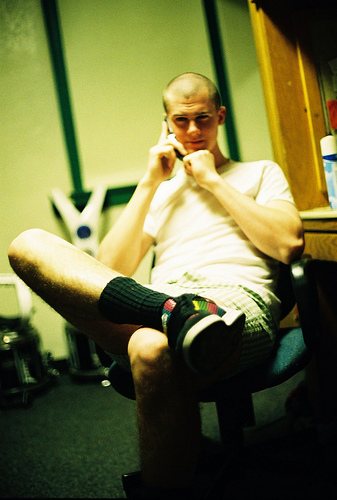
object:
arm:
[206, 179, 305, 264]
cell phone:
[161, 115, 184, 159]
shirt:
[140, 157, 295, 312]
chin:
[181, 147, 213, 154]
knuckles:
[181, 146, 216, 162]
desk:
[289, 207, 335, 336]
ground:
[231, 84, 254, 118]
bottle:
[319, 134, 337, 210]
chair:
[102, 226, 326, 494]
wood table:
[297, 205, 335, 262]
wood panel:
[249, 0, 323, 215]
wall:
[61, 0, 132, 86]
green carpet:
[10, 369, 121, 450]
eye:
[174, 115, 187, 124]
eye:
[197, 113, 210, 121]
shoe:
[161, 292, 248, 377]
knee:
[8, 227, 57, 278]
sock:
[96, 269, 173, 323]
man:
[5, 68, 305, 500]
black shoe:
[160, 291, 247, 383]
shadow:
[250, 1, 335, 96]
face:
[168, 94, 216, 159]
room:
[0, 0, 337, 500]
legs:
[7, 226, 245, 403]